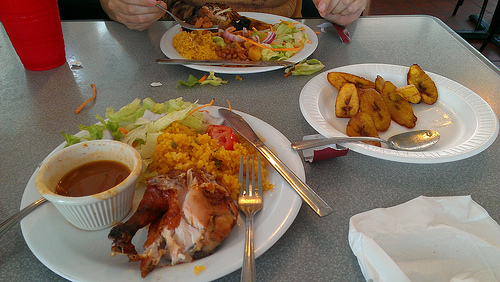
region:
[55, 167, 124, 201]
some type of brown sauce in white bowl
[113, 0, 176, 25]
the hand of the person holding silver fork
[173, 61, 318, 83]
pieces of lettuce and shreds of carrot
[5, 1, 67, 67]
a large disposable red plastic cup on table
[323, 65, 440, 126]
several sections of cooked apples on plate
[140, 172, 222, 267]
a piece of chicken on white plate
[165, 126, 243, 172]
a yellow rice with a tomato on the plate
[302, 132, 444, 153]
a silver spoon on the white plate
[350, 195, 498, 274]
some white napkins on the dinner tablke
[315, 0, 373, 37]
a piece of red paper under person's hand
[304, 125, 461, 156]
large silver spoon on plate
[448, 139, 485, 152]
edge of white plate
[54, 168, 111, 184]
brown gravy in white cup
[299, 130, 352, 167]
piece of purple and white paper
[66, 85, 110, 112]
orange carrot sliver on table top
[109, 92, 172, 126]
pieces of green lettuce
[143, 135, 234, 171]
yellow rice with peas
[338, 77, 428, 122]
yellow fried plantains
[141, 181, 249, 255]
juicy piece of grilled chicken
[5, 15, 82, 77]
red plastic cup on table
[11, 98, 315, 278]
a plate full of food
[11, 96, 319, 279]
a plate of fried chicken and rice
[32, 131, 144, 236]
a container of barbecue sauce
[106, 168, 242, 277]
a piece of barbecue chicken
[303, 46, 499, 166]
a plate of fried plantains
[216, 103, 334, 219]
a silver colored knife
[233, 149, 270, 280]
a silver colored fork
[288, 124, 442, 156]
a silver colored spoon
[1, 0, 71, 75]
a red plastic cup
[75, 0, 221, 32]
a hand holding a fork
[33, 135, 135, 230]
dipping sauce in a white cup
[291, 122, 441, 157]
silver spoon in a white bowl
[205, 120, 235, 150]
red tomato slice sitting on rice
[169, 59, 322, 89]
lettuce on the table top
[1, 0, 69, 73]
red, plastic cup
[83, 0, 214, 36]
person holding a silver fork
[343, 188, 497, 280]
white paper wrapper on the table top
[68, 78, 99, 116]
long carrot piece on the table top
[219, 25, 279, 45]
onion slices on top of lettuce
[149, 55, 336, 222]
two silver knives balancing on plate edges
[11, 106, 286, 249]
A plate of food on the table.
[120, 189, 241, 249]
Chicken on the plate.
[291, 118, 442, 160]
A spoon on the white plate.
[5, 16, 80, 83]
A red cup on the table.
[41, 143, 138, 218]
Gravy in the small bowl.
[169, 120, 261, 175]
Yellow rice next to the chicken.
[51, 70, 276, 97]
Lettuce on the table.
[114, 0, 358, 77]
A person eating food.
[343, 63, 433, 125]
Plantains on the paper plate.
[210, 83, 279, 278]
A fork and knife on top of the plate.